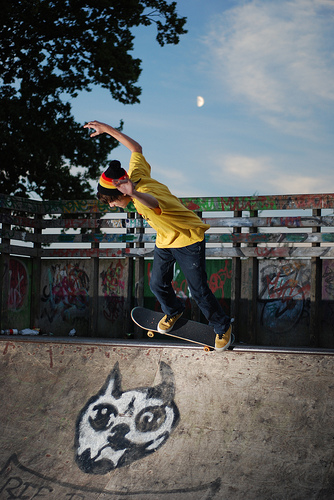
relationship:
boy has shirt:
[84, 119, 235, 356] [124, 151, 209, 247]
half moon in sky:
[195, 93, 204, 109] [6, 5, 333, 260]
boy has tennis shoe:
[84, 119, 235, 356] [156, 309, 192, 335]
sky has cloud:
[6, 5, 333, 260] [202, 7, 331, 190]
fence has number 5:
[3, 194, 333, 355] [260, 261, 306, 337]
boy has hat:
[84, 119, 235, 356] [92, 159, 129, 197]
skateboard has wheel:
[129, 301, 235, 354] [147, 329, 156, 340]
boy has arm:
[84, 119, 235, 356] [85, 118, 150, 178]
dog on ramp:
[70, 360, 186, 475] [1, 331, 333, 500]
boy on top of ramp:
[84, 119, 235, 356] [1, 331, 333, 500]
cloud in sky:
[202, 7, 331, 190] [6, 5, 333, 260]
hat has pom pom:
[92, 159, 129, 197] [107, 157, 123, 170]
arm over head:
[85, 118, 150, 178] [97, 162, 132, 195]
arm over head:
[111, 174, 162, 210] [97, 162, 132, 195]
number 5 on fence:
[260, 261, 306, 337] [3, 194, 333, 355]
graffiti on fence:
[38, 262, 96, 339] [3, 194, 333, 355]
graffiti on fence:
[99, 261, 128, 326] [3, 194, 333, 355]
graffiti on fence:
[9, 257, 36, 322] [3, 194, 333, 355]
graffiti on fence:
[138, 255, 236, 340] [3, 194, 333, 355]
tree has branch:
[2, 3, 189, 234] [20, 154, 104, 239]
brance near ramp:
[2, 158, 45, 247] [1, 331, 333, 500]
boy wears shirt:
[84, 119, 235, 356] [124, 151, 209, 247]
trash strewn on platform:
[5, 324, 18, 339] [4, 323, 330, 354]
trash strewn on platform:
[19, 324, 46, 336] [4, 323, 330, 354]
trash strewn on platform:
[67, 327, 77, 336] [4, 323, 330, 354]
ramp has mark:
[1, 331, 333, 500] [244, 395, 264, 412]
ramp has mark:
[1, 331, 333, 500] [45, 344, 61, 369]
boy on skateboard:
[84, 119, 235, 356] [129, 301, 235, 354]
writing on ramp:
[4, 469, 86, 500] [1, 331, 333, 500]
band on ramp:
[4, 338, 334, 363] [1, 331, 333, 500]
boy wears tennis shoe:
[84, 119, 235, 356] [156, 309, 192, 335]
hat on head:
[92, 159, 129, 197] [97, 162, 132, 195]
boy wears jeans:
[84, 119, 235, 356] [146, 246, 229, 338]